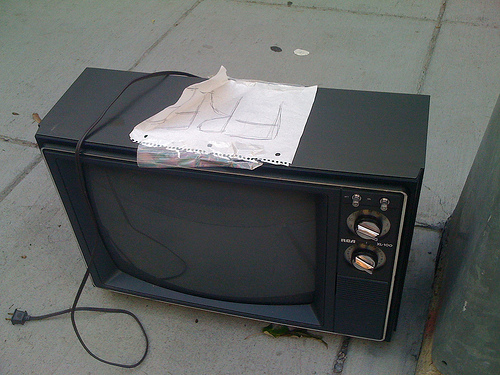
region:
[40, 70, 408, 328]
An analog television set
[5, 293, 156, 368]
An analog television set cable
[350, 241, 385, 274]
An analog television set tunning knob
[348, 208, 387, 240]
An analog television set tunning knob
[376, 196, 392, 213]
An analog television set tunning knob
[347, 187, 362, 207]
An analog television set tunning knob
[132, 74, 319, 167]
Free paper sign on the tv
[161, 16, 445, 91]
A cemented tile wall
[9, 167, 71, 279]
An analog television set tunning knob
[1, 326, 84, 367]
An analog television set tunning knob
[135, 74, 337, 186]
white paper on tv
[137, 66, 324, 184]
paper is old and rumpled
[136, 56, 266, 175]
black writing on paper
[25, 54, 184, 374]
black cord on tv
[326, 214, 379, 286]
grey knobs on tv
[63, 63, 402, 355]
black frame for tv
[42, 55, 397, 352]
CRT tv on grey sidewalk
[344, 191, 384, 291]
adjustment knobs on control panel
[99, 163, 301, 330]
curved screen on tv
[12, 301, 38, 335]
two prong plug for tv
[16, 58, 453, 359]
a television outside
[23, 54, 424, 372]
a television on the sidewalk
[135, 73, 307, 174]
a sign that says Free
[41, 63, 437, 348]
a free television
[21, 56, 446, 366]
a television with a sign on it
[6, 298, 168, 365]
a cord on the sidewalk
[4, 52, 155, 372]
a cord to a television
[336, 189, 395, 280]
controls on a television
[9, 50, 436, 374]
a free old tv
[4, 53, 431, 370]
an old black television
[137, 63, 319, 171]
Sign on the television.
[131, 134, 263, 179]
Tape attaching paper to television.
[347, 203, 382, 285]
Knob on the television.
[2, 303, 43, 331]
Plug in to the television.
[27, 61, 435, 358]
Television on the ground.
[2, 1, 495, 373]
Concrete squares on the ground.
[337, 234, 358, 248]
White writing on the television.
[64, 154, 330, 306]
Glass on the television screen.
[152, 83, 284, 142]
Gray writing on the paper.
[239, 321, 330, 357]
Green leaf on the ground.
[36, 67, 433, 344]
Old black television sitting on sidewalk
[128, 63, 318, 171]
Sheet of notebook paper taped to television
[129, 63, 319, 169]
Handwritten sign saying "FREE" on top of television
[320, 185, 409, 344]
Panel of television with channel-changer dials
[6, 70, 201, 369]
Electrical cord attached to television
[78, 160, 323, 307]
Old-fashioned screen of television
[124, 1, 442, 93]
Square section of cement sidewalk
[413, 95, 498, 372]
Gray wall beside television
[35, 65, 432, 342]
Free television sitting outside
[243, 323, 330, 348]
Green leaf lying on sidewalk in front of television